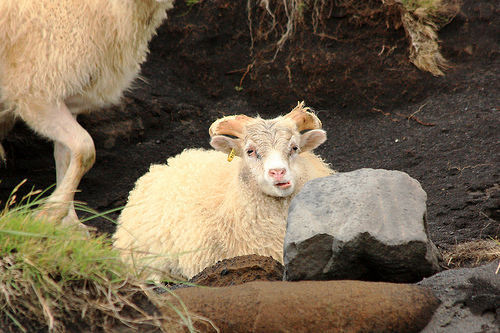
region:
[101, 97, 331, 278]
Sheep is looking at the camera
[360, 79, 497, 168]
The dirt is very wet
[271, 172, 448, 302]
Large rock sitting by the goat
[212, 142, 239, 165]
The goat has an ear tag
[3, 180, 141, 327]
Grass growing in the dirt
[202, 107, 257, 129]
Goat has large horns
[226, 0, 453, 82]
Roots hanging down the hill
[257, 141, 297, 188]
The goat is chewing something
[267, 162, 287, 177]
Goats nose is pink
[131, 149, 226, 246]
The goat is fluffy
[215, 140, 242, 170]
Tag in the ear.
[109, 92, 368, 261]
Sheep on the ground.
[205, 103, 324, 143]
Horns on the head.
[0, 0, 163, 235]
A sheep is walking.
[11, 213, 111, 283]
Small patch of grass.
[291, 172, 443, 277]
The rock is grey.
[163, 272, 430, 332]
The rock is brown.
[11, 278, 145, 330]
Brown on the grass.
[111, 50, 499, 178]
The ground is mostly dirt.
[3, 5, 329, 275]
The sheep are white.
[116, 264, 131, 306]
part of a grass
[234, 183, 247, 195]
body of a sheep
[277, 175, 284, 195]
mouth of a sheep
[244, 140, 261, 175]
eye of a sheep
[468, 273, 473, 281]
edge of a rock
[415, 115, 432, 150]
part of a root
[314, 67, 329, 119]
part of the soil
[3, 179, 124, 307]
a grass under the goat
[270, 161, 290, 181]
nose of the sheep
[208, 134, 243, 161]
ear of the sheep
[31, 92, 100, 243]
a goat lifting his leg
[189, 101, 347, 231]
the goat is seeing the camera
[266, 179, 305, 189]
mouth of the goat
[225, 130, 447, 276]
stone in front of the sheep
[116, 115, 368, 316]
a goat is lying the rock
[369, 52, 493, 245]
a place full of rock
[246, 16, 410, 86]
root of the plant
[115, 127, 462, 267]
The rock is next to the goat.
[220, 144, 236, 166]
The goat is tagged on his ear.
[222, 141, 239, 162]
The tag is yellow.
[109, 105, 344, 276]
The goat is white.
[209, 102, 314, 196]
The face is white.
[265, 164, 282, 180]
His nose is pink.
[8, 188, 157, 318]
The grass is green.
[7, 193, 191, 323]
The grass is long.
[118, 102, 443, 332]
The goat is laying down.